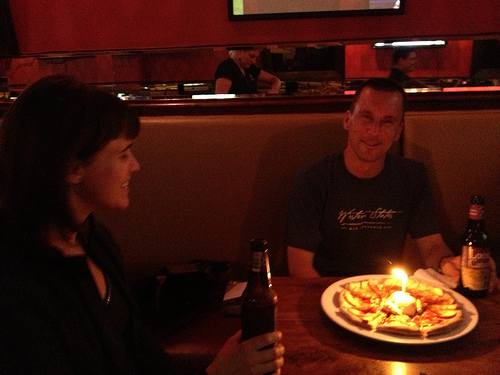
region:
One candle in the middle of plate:
[366, 272, 431, 314]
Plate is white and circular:
[308, 267, 456, 366]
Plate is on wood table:
[286, 284, 370, 363]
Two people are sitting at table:
[39, 75, 425, 195]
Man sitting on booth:
[288, 113, 450, 225]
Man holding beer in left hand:
[414, 175, 478, 297]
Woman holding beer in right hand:
[128, 211, 293, 355]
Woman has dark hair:
[26, 92, 113, 222]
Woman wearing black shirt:
[51, 239, 151, 338]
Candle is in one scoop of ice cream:
[380, 269, 433, 346]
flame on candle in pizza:
[385, 259, 421, 294]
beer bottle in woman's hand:
[232, 229, 284, 374]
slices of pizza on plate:
[335, 294, 462, 336]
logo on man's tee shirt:
[325, 204, 413, 241]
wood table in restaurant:
[295, 334, 345, 368]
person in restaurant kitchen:
[197, 33, 304, 113]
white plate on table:
[313, 264, 485, 349]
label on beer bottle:
[455, 239, 496, 299]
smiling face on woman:
[108, 135, 139, 214]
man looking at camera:
[345, 83, 413, 165]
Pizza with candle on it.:
[328, 247, 460, 358]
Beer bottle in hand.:
[224, 222, 284, 372]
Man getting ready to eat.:
[272, 72, 465, 301]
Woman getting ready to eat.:
[10, 87, 401, 371]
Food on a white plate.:
[316, 252, 467, 372]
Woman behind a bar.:
[171, 52, 291, 120]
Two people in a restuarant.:
[73, 94, 440, 367]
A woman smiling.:
[40, 92, 207, 305]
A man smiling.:
[267, 81, 452, 351]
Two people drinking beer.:
[25, 82, 480, 359]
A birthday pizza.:
[312, 252, 487, 359]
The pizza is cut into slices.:
[315, 255, 482, 370]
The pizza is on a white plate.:
[320, 260, 480, 355]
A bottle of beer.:
[455, 190, 491, 300]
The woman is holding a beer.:
[190, 215, 295, 370]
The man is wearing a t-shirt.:
[271, 80, 446, 285]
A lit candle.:
[381, 255, 411, 295]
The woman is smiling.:
[0, 70, 162, 275]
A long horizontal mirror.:
[0, 35, 485, 112]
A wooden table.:
[235, 270, 497, 373]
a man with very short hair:
[311, 75, 446, 192]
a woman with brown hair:
[22, 50, 159, 295]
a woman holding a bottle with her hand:
[13, 127, 285, 372]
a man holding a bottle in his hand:
[289, 80, 492, 322]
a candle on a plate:
[367, 267, 439, 309]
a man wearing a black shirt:
[292, 81, 448, 273]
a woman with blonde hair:
[210, 39, 282, 80]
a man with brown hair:
[381, 44, 451, 79]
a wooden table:
[241, 197, 498, 374]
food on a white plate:
[328, 267, 464, 352]